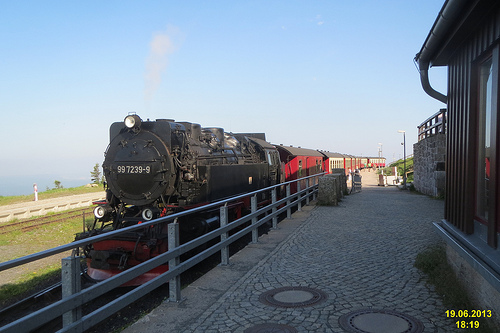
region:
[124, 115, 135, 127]
the white headlight on a train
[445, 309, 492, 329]
the time stamp on the corner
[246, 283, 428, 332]
circular designs in the concrete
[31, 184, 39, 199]
a pole on the side of the road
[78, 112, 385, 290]
a train coming around the corner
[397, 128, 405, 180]
a lamp post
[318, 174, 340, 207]
a large concrete block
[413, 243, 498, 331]
shrubbery along the building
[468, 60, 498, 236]
the windows on the front of a building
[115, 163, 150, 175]
the numbers on the front of a train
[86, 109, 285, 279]
The train engine is black and red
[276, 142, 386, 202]
The train cars are red and white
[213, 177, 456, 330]
Grey cobble stone walk way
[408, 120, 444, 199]
The wall is stone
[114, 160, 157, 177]
White numbers on front of train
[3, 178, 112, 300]
Grass next to the tracks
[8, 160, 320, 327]
The fence is grey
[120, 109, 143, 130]
White horn on top of train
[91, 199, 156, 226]
Round lights on front of train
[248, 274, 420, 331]
Grates on path way are round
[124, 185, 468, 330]
a train station platform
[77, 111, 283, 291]
a black and red train engine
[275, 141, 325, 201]
a red passenger train car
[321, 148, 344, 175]
a red and white passenger train car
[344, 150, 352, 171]
a red and white passenger train car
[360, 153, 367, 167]
a red and white passenger train car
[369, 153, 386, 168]
a red and white passenger train car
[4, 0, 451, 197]
a clear blue sky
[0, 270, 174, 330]
a set of train tracks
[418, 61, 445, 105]
a gutter pipe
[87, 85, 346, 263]
A train is on the track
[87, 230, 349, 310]
a fence is next to the train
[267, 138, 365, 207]
The back of the train is red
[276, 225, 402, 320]
The concrete is gray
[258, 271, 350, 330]
Circles are on the ground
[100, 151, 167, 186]
Numbers are on the front of the train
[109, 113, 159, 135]
A light is on the front of the train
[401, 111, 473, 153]
A bridge is next to the train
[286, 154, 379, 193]
Windows are on the train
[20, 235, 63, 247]
Grass is next to the track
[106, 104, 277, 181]
black train engine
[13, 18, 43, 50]
white clouds in blue sky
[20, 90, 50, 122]
white clouds in blue sky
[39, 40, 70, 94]
white clouds in blue sky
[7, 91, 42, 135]
white clouds in blue sky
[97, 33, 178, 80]
white clouds in blue sky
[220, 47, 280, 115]
white clouds in blue sky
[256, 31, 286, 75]
white clouds in blue sky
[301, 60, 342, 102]
white clouds in blue sky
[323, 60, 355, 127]
white clouds in blue sky